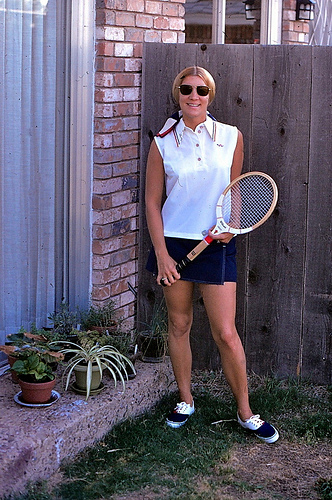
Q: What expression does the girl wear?
A: Smile.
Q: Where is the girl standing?
A: In front of fence.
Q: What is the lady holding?
A: Tennis racket.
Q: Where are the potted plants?
A: Beside girl.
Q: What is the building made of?
A: Brick.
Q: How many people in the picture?
A: One.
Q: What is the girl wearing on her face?
A: Sunglasses.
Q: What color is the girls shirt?
A: White.